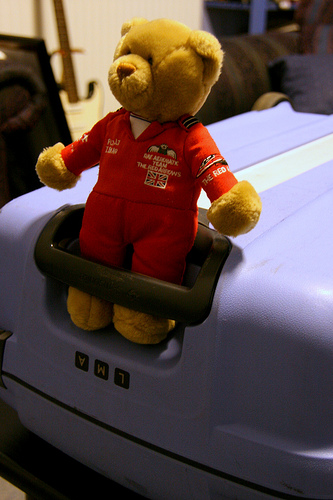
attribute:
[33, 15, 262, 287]
teddy bear — brown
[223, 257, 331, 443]
luggage — voilet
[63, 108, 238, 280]
overalls — black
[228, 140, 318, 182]
stripe — white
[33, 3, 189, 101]
wall — white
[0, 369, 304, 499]
stripe — black 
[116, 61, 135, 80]
nose — brown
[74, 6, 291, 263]
doll — brown 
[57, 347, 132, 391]
letters — black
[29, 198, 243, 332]
handle — black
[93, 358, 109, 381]
letter — black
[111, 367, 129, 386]
letter — black